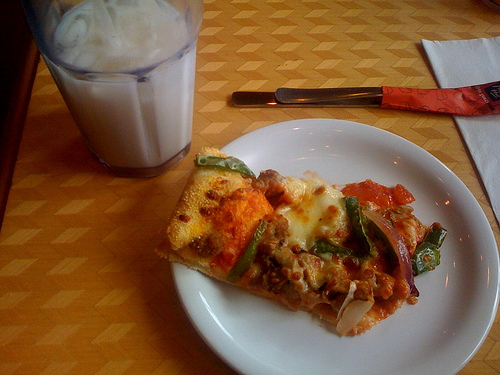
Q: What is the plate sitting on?
A: Table.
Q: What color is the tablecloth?
A: Gold.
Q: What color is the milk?
A: White.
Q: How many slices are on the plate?
A: 1.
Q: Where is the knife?
A: In the napkin.